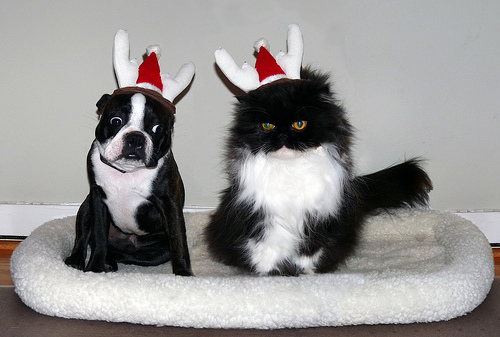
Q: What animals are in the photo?
A: Cat and Dog.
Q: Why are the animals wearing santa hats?
A: Christmas.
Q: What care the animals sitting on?
A: Pet bed.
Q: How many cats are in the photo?
A: 1.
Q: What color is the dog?
A: White and black.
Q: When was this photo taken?
A: Daytime.